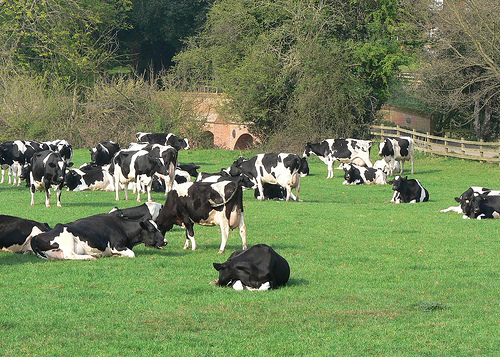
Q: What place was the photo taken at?
A: It was taken at the field.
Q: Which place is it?
A: It is a field.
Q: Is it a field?
A: Yes, it is a field.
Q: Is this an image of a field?
A: Yes, it is showing a field.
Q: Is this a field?
A: Yes, it is a field.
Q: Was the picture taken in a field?
A: Yes, it was taken in a field.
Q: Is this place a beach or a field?
A: It is a field.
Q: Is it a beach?
A: No, it is a field.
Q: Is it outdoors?
A: Yes, it is outdoors.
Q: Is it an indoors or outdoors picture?
A: It is outdoors.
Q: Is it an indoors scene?
A: No, it is outdoors.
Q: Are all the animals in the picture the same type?
A: Yes, all the animals are cows.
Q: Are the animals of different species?
A: No, all the animals are cows.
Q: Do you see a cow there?
A: Yes, there is a cow.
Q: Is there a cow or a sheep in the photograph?
A: Yes, there is a cow.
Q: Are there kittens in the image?
A: No, there are no kittens.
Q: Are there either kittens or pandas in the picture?
A: No, there are no kittens or pandas.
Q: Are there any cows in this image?
A: Yes, there is a cow.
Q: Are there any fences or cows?
A: Yes, there is a cow.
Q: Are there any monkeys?
A: No, there are no monkeys.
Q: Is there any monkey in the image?
A: No, there are no monkeys.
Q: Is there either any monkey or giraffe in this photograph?
A: No, there are no monkeys or giraffes.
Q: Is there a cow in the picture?
A: Yes, there is a cow.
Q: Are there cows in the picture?
A: Yes, there is a cow.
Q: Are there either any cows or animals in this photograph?
A: Yes, there is a cow.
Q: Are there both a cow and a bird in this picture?
A: No, there is a cow but no birds.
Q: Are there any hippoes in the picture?
A: No, there are no hippoes.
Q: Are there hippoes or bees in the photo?
A: No, there are no hippoes or bees.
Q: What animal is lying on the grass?
A: The cow is lying on the grass.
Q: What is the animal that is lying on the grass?
A: The animal is a cow.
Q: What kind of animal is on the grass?
A: The animal is a cow.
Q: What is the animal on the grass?
A: The animal is a cow.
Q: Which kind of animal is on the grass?
A: The animal is a cow.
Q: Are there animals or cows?
A: Yes, there is a cow.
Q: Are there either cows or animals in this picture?
A: Yes, there is a cow.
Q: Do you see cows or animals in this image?
A: Yes, there is a cow.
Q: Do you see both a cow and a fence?
A: Yes, there are both a cow and a fence.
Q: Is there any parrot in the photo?
A: No, there are no parrots.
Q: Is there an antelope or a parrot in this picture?
A: No, there are no parrots or antelopes.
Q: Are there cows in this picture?
A: Yes, there is a cow.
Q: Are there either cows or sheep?
A: Yes, there is a cow.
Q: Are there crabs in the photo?
A: No, there are no crabs.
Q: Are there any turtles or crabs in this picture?
A: No, there are no crabs or turtles.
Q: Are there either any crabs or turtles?
A: No, there are no crabs or turtles.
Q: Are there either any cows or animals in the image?
A: Yes, there is a cow.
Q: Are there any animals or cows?
A: Yes, there is a cow.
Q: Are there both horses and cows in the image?
A: No, there is a cow but no horses.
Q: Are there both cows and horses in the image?
A: No, there is a cow but no horses.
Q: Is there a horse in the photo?
A: No, there are no horses.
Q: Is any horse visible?
A: No, there are no horses.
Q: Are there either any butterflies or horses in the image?
A: No, there are no horses or butterflies.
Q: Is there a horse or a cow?
A: Yes, there is a cow.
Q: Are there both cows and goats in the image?
A: No, there is a cow but no goats.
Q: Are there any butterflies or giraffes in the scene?
A: No, there are no giraffes or butterflies.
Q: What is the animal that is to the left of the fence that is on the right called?
A: The animal is a cow.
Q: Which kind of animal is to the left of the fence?
A: The animal is a cow.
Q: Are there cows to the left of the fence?
A: Yes, there is a cow to the left of the fence.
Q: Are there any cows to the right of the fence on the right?
A: No, the cow is to the left of the fence.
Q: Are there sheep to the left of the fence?
A: No, there is a cow to the left of the fence.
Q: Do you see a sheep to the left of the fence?
A: No, there is a cow to the left of the fence.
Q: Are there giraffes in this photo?
A: No, there are no giraffes.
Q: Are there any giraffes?
A: No, there are no giraffes.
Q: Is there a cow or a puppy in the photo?
A: Yes, there is a cow.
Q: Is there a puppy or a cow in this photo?
A: Yes, there is a cow.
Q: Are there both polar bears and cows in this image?
A: No, there is a cow but no polar bears.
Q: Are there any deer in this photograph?
A: No, there are no deer.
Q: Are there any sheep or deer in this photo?
A: No, there are no deer or sheep.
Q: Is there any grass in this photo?
A: Yes, there is grass.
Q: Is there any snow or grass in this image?
A: Yes, there is grass.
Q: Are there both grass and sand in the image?
A: No, there is grass but no sand.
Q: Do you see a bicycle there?
A: No, there are no bicycles.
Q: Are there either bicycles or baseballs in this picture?
A: No, there are no bicycles or baseballs.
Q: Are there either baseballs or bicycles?
A: No, there are no bicycles or baseballs.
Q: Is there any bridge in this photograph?
A: Yes, there is a bridge.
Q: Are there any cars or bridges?
A: Yes, there is a bridge.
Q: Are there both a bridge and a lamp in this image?
A: No, there is a bridge but no lamps.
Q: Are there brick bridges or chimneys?
A: Yes, there is a brick bridge.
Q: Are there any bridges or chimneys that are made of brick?
A: Yes, the bridge is made of brick.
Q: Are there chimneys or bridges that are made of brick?
A: Yes, the bridge is made of brick.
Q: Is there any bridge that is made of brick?
A: Yes, there is a bridge that is made of brick.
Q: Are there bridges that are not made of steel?
A: Yes, there is a bridge that is made of brick.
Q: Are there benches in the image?
A: No, there are no benches.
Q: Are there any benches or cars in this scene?
A: No, there are no benches or cars.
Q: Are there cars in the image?
A: No, there are no cars.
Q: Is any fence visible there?
A: Yes, there is a fence.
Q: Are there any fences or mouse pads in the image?
A: Yes, there is a fence.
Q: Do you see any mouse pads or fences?
A: Yes, there is a fence.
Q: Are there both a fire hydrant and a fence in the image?
A: No, there is a fence but no fire hydrants.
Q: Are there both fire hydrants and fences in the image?
A: No, there is a fence but no fire hydrants.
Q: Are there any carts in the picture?
A: No, there are no carts.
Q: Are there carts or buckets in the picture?
A: No, there are no carts or buckets.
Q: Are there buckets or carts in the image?
A: No, there are no carts or buckets.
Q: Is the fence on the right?
A: Yes, the fence is on the right of the image.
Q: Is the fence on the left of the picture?
A: No, the fence is on the right of the image.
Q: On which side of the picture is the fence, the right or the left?
A: The fence is on the right of the image.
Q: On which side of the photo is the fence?
A: The fence is on the right of the image.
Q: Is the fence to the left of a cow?
A: No, the fence is to the right of a cow.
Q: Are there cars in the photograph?
A: No, there are no cars.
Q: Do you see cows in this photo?
A: Yes, there is a cow.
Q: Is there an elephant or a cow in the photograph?
A: Yes, there is a cow.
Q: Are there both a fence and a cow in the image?
A: Yes, there are both a cow and a fence.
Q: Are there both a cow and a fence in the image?
A: Yes, there are both a cow and a fence.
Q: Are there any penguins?
A: No, there are no penguins.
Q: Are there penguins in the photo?
A: No, there are no penguins.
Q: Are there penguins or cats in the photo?
A: No, there are no penguins or cats.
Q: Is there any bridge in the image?
A: Yes, there is a bridge.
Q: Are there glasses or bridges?
A: Yes, there is a bridge.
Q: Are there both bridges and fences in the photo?
A: Yes, there are both a bridge and a fence.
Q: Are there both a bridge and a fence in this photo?
A: Yes, there are both a bridge and a fence.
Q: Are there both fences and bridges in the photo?
A: Yes, there are both a bridge and a fence.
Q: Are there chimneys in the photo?
A: No, there are no chimneys.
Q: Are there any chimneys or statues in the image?
A: No, there are no chimneys or statues.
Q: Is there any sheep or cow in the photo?
A: Yes, there is a cow.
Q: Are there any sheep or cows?
A: Yes, there is a cow.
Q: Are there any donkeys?
A: No, there are no donkeys.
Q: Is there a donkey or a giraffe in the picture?
A: No, there are no donkeys or giraffes.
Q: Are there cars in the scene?
A: No, there are no cars.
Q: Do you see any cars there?
A: No, there are no cars.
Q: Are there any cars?
A: No, there are no cars.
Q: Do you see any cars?
A: No, there are no cars.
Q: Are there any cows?
A: Yes, there is a cow.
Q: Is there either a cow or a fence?
A: Yes, there is a cow.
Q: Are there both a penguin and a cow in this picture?
A: No, there is a cow but no penguins.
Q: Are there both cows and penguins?
A: No, there is a cow but no penguins.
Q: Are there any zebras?
A: No, there are no zebras.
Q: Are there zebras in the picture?
A: No, there are no zebras.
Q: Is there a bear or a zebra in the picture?
A: No, there are no zebras or bears.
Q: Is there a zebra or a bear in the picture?
A: No, there are no zebras or bears.